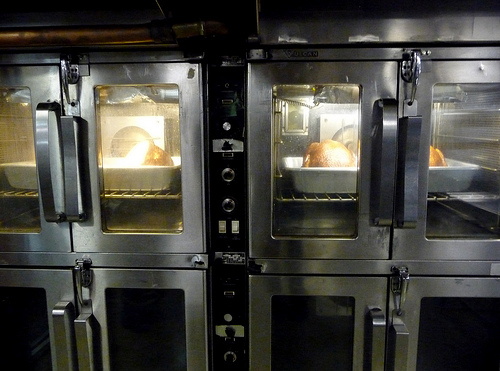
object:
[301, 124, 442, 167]
food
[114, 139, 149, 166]
light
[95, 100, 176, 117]
light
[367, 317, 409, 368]
handles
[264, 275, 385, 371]
doors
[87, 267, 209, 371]
doors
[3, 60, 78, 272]
doors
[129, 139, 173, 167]
food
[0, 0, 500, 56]
pipe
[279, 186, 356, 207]
grate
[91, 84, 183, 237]
window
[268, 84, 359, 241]
window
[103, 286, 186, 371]
window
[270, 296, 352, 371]
window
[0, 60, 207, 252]
oven door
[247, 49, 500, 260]
oven door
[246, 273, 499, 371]
oven door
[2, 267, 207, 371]
oven door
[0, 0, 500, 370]
commercial ovens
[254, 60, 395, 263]
doors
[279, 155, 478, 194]
pan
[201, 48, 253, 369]
switches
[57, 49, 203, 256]
doors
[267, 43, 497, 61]
sticker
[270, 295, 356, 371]
dark window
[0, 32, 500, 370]
oven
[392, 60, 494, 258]
doors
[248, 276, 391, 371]
doors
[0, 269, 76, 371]
doors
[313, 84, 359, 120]
light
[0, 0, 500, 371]
silver door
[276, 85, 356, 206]
window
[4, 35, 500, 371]
ovens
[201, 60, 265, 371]
panel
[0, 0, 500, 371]
rack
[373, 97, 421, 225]
handles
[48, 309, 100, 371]
handles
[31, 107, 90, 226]
handles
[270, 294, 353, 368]
glass